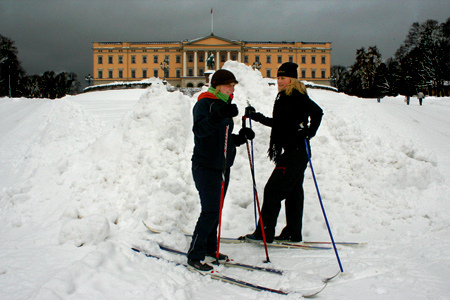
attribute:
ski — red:
[131, 227, 302, 297]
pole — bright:
[207, 119, 241, 263]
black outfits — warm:
[176, 64, 397, 233]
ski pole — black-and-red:
[239, 106, 294, 267]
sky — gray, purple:
[269, 15, 378, 45]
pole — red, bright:
[299, 135, 383, 277]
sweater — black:
[269, 93, 307, 157]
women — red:
[195, 58, 321, 153]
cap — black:
[209, 66, 241, 88]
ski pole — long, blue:
[300, 129, 345, 272]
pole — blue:
[302, 140, 348, 277]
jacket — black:
[248, 85, 325, 160]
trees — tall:
[327, 16, 449, 113]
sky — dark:
[6, 6, 449, 62]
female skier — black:
[243, 55, 324, 247]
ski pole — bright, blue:
[302, 124, 346, 275]